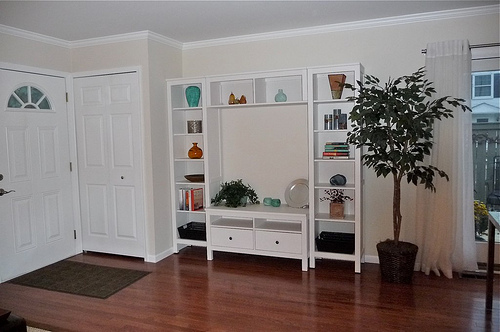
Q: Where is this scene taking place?
A: In a livingroom.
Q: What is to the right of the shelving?
A: A potted tree.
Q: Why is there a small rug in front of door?
A: For people to wipe their feet.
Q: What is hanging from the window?
A: Curtains.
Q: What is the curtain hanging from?
A: A rod.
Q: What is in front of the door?
A: A rug.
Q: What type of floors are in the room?
A: Hardwoods.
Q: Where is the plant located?
A: By the window.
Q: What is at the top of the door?
A: A window.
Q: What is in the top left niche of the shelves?
A: A vase.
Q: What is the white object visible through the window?
A: A house.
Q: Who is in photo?
A: Nobody.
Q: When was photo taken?
A: Daytime.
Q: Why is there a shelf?
A: Holding things.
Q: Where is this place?
A: House.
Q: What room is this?
A: Living room.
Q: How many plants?
A: One.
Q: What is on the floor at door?
A: Mat.